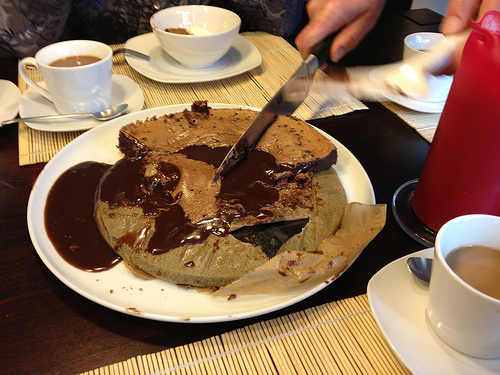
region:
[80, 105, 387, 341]
a cake on a plate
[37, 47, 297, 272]
a cake on a plate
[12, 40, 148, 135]
Cup of coffee on a saucer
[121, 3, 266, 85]
Cup of coffee on a saucer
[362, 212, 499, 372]
Cup of coffee on a saucer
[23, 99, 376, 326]
Cake being cut with a knife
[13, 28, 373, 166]
A wicker placemat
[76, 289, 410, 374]
A wicker placemat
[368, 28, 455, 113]
A cup of coffee on a saucer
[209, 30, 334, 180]
A large knife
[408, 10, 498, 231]
A red pillar candle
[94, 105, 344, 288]
A large chocolate cake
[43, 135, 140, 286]
a pool of melted chocolate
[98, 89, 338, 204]
a gooey dessert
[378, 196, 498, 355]
a small cup of coffee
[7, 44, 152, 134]
a matching cup and saucer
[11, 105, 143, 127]
a small silver tea spoon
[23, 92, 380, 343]
a round white plate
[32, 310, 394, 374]
a thin wood placemat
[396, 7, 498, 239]
a tall red candle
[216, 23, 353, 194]
a black handled chef knife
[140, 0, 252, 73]
a small white bowl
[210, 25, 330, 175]
knife cutting chocolate desert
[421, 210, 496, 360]
half cup of coffee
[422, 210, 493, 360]
white cup sitting on saucer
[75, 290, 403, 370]
beige bamboo table mate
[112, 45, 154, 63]
fork laying on white saucer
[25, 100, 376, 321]
white plate with desert on it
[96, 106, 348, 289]
hot fudge sitting on plate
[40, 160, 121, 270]
melted chocolate on white plate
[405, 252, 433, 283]
spoon sitting on white saucer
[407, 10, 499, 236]
bottle of punch sitting on table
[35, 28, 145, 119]
cup of coffe on a saucer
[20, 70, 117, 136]
white saucer with a cup on top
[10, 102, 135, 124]
silver spoon on a saucer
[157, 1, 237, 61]
white cup on a saucer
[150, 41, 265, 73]
white saucer with a cup on top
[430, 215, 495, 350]
cup of coffe on top of a white plate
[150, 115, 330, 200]
desert on a white plate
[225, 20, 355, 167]
silver knife cutting a desert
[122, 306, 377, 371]
place mate on a table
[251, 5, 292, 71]
place mate on brown table